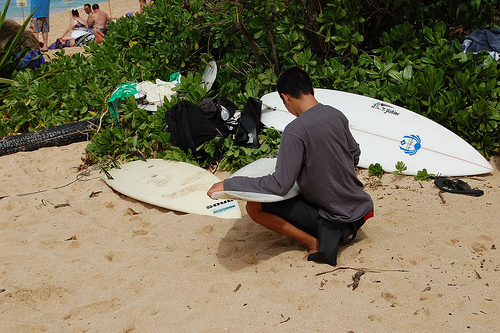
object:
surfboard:
[100, 157, 244, 219]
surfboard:
[260, 89, 497, 179]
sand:
[0, 215, 205, 332]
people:
[56, 4, 110, 48]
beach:
[14, 18, 70, 47]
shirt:
[223, 105, 374, 221]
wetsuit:
[197, 92, 263, 150]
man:
[208, 68, 373, 263]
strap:
[433, 176, 487, 198]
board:
[212, 157, 301, 203]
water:
[3, 1, 28, 18]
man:
[29, 2, 51, 53]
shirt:
[30, 0, 51, 17]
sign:
[15, 1, 30, 23]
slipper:
[435, 177, 486, 197]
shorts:
[30, 13, 51, 33]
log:
[1, 118, 105, 159]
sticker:
[399, 132, 422, 157]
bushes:
[158, 2, 239, 34]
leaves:
[333, 27, 364, 57]